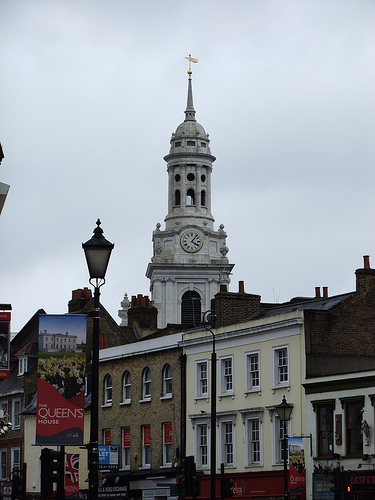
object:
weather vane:
[185, 54, 198, 79]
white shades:
[119, 427, 150, 472]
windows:
[99, 421, 173, 472]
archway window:
[181, 290, 201, 324]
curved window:
[100, 373, 112, 407]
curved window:
[119, 370, 132, 407]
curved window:
[139, 366, 152, 402]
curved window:
[159, 363, 172, 400]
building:
[91, 323, 182, 500]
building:
[178, 256, 375, 499]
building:
[302, 370, 375, 500]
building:
[0, 288, 155, 499]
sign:
[34, 314, 87, 447]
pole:
[56, 442, 65, 499]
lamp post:
[81, 217, 115, 500]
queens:
[36, 314, 87, 446]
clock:
[180, 230, 204, 253]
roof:
[328, 255, 375, 329]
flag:
[65, 452, 80, 499]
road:
[73, 484, 196, 500]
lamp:
[274, 395, 295, 421]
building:
[0, 254, 375, 499]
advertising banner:
[35, 313, 86, 445]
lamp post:
[273, 395, 295, 499]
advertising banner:
[287, 435, 307, 495]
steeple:
[184, 54, 199, 122]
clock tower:
[145, 54, 234, 329]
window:
[187, 188, 196, 205]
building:
[98, 348, 181, 481]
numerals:
[183, 233, 200, 251]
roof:
[183, 255, 374, 354]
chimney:
[353, 255, 374, 296]